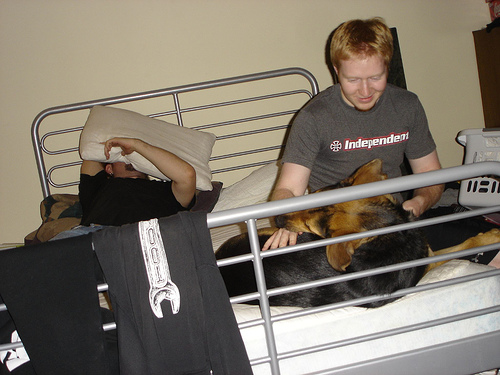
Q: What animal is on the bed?
A: Dog.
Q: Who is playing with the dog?
A: A man.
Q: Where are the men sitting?
A: On the bed.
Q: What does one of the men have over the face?
A: Pillow.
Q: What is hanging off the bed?
A: Shirt.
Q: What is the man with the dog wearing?
A: A tshirt.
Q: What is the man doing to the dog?
A: Petting.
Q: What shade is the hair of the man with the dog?
A: Red.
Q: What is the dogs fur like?
A: Brown and black.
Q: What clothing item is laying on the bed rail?
A: A shirt.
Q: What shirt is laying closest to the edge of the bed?
A: The black shirt.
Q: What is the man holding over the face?
A: A pillow.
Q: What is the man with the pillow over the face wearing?
A: A black shirt.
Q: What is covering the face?
A: A pillow.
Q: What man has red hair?
A: The man in the gray shirt.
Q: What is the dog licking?
A: The hand.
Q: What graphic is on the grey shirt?
A: A tool.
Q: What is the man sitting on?
A: A mattress.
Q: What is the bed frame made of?
A: Metal.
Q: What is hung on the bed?
A: Clothes.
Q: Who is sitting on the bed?
A: Two men.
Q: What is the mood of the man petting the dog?
A: Happy.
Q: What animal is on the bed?
A: A dog.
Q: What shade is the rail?
A: Silver.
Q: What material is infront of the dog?
A: Metal.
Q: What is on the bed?
A: A silver rail.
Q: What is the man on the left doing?
A: Putting a pillow on his face.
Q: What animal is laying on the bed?
A: A brown and black dog.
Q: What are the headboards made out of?
A: Silver metal.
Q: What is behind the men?
A: A plain wall.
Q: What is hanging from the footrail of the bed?
A: Clothes.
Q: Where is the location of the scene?
A: A bedroom.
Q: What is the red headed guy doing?
A: Playing with dogs.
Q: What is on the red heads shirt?
A: Independence.